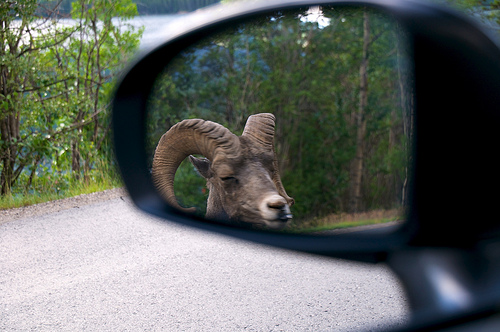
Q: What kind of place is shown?
A: It is a road.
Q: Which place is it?
A: It is a road.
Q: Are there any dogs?
A: No, there are no dogs.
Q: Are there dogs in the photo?
A: No, there are no dogs.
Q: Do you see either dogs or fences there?
A: No, there are no dogs or fences.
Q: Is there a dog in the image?
A: No, there are no dogs.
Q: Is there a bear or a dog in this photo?
A: No, there are no dogs or bears.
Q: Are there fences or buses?
A: No, there are no fences or buses.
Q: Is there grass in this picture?
A: Yes, there is grass.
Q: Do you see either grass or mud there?
A: Yes, there is grass.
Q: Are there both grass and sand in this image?
A: No, there is grass but no sand.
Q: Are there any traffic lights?
A: No, there are no traffic lights.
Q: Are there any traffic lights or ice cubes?
A: No, there are no traffic lights or ice cubes.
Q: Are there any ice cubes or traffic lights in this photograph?
A: No, there are no traffic lights or ice cubes.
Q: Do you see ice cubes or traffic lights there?
A: No, there are no traffic lights or ice cubes.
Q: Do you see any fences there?
A: No, there are no fences.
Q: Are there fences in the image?
A: No, there are no fences.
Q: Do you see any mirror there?
A: Yes, there is a mirror.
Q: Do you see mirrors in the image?
A: Yes, there is a mirror.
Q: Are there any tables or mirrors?
A: Yes, there is a mirror.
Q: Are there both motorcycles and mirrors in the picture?
A: No, there is a mirror but no motorcycles.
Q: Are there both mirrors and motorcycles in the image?
A: No, there is a mirror but no motorcycles.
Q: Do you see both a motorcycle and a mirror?
A: No, there is a mirror but no motorcycles.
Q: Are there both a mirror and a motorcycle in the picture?
A: No, there is a mirror but no motorcycles.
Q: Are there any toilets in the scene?
A: No, there are no toilets.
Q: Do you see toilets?
A: No, there are no toilets.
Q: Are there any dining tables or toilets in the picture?
A: No, there are no toilets or dining tables.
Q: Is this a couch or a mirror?
A: This is a mirror.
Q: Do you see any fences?
A: No, there are no fences.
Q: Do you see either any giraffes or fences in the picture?
A: No, there are no fences or giraffes.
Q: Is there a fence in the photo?
A: No, there are no fences.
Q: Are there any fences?
A: No, there are no fences.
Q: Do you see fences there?
A: No, there are no fences.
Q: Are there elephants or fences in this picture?
A: No, there are no fences or elephants.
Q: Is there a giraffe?
A: No, there are no giraffes.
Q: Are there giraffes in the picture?
A: No, there are no giraffes.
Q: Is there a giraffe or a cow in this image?
A: No, there are no giraffes or cows.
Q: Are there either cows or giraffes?
A: No, there are no giraffes or cows.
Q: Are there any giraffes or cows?
A: No, there are no giraffes or cows.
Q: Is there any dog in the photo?
A: No, there are no dogs.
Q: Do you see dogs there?
A: No, there are no dogs.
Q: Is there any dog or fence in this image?
A: No, there are no dogs or fences.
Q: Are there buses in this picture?
A: No, there are no buses.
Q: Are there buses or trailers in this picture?
A: No, there are no buses or trailers.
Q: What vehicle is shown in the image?
A: The vehicle is a car.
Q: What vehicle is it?
A: The vehicle is a car.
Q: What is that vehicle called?
A: This is a car.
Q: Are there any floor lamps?
A: No, there are no floor lamps.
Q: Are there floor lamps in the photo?
A: No, there are no floor lamps.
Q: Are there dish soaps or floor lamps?
A: No, there are no floor lamps or dish soaps.